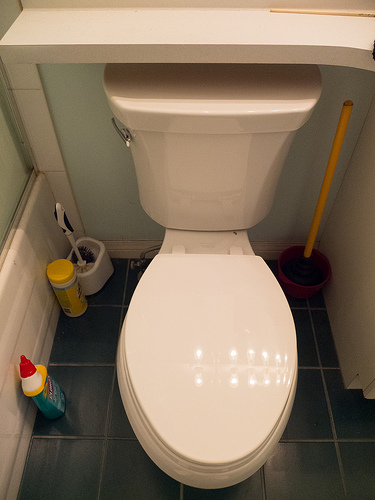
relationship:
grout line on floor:
[28, 432, 135, 441] [302, 315, 337, 497]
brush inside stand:
[52, 200, 95, 271] [64, 236, 114, 296]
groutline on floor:
[46, 358, 116, 370] [17, 257, 374, 498]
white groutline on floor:
[94, 261, 135, 481] [17, 257, 374, 498]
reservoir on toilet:
[102, 63, 324, 230] [102, 63, 326, 487]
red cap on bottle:
[15, 352, 38, 379] [15, 351, 69, 419]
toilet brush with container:
[51, 200, 97, 273] [66, 235, 116, 297]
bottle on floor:
[46, 258, 87, 317] [17, 257, 374, 498]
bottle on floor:
[15, 351, 69, 419] [17, 257, 374, 498]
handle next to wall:
[301, 98, 356, 259] [35, 63, 373, 260]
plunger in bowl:
[282, 247, 318, 286] [271, 249, 332, 296]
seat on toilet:
[120, 240, 305, 459] [102, 63, 326, 487]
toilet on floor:
[102, 63, 326, 487] [301, 306, 325, 498]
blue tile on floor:
[319, 356, 369, 457] [30, 243, 374, 461]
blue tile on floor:
[7, 228, 372, 498] [17, 257, 374, 498]